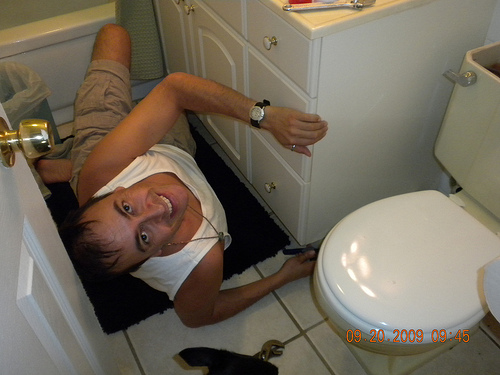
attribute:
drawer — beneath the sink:
[243, 3, 317, 95]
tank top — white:
[109, 141, 231, 295]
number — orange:
[351, 327, 363, 342]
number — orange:
[354, 325, 361, 343]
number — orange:
[367, 326, 377, 346]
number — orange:
[369, 328, 378, 341]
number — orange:
[354, 327, 362, 340]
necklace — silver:
[134, 192, 226, 250]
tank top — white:
[81, 128, 236, 305]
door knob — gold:
[1, 111, 57, 167]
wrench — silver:
[214, 334, 291, 373]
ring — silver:
[288, 140, 298, 154]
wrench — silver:
[279, 0, 375, 11]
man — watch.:
[61, 24, 324, 324]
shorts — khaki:
[72, 46, 204, 168]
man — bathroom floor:
[44, 26, 317, 329]